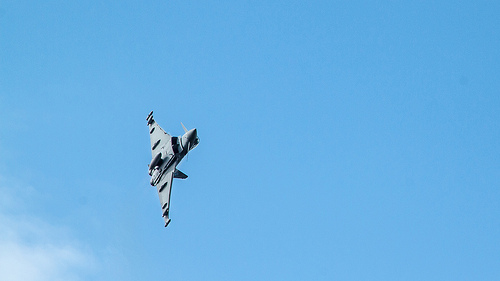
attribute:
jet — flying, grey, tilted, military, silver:
[143, 104, 198, 233]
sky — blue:
[4, 6, 495, 281]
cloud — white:
[8, 182, 64, 279]